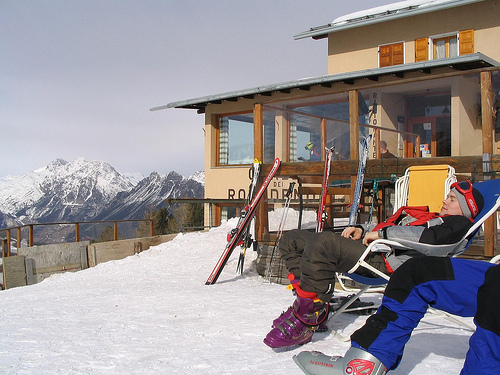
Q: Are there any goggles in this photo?
A: Yes, there are goggles.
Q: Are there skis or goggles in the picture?
A: Yes, there are goggles.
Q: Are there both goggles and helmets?
A: No, there are goggles but no helmets.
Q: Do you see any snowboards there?
A: No, there are no snowboards.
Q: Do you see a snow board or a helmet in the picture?
A: No, there are no snowboards or helmets.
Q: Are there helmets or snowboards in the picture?
A: No, there are no snowboards or helmets.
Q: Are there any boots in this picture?
A: Yes, there are boots.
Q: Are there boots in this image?
A: Yes, there are boots.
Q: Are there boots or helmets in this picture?
A: Yes, there are boots.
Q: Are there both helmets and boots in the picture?
A: No, there are boots but no helmets.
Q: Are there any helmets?
A: No, there are no helmets.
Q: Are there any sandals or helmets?
A: No, there are no helmets or sandals.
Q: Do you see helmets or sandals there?
A: No, there are no helmets or sandals.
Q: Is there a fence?
A: Yes, there is a fence.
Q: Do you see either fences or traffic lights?
A: Yes, there is a fence.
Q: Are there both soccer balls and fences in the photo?
A: No, there is a fence but no soccer balls.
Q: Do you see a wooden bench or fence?
A: Yes, there is a wood fence.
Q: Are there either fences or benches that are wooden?
A: Yes, the fence is wooden.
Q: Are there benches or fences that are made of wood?
A: Yes, the fence is made of wood.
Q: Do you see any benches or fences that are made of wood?
A: Yes, the fence is made of wood.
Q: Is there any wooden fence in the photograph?
A: Yes, there is a wood fence.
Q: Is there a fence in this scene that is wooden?
A: Yes, there is a fence that is wooden.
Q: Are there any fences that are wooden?
A: Yes, there is a fence that is wooden.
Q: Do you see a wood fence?
A: Yes, there is a fence that is made of wood.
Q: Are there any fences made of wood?
A: Yes, there is a fence that is made of wood.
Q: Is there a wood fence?
A: Yes, there is a fence that is made of wood.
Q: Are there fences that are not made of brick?
A: Yes, there is a fence that is made of wood.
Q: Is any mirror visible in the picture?
A: No, there are no mirrors.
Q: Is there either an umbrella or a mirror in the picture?
A: No, there are no mirrors or umbrellas.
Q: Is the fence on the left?
A: Yes, the fence is on the left of the image.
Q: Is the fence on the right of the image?
A: No, the fence is on the left of the image.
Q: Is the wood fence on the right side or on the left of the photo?
A: The fence is on the left of the image.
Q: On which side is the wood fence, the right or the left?
A: The fence is on the left of the image.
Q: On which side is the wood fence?
A: The fence is on the left of the image.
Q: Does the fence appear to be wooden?
A: Yes, the fence is wooden.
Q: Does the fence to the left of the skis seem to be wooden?
A: Yes, the fence is wooden.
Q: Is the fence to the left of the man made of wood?
A: Yes, the fence is made of wood.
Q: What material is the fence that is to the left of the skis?
A: The fence is made of wood.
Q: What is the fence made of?
A: The fence is made of wood.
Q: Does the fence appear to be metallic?
A: No, the fence is wooden.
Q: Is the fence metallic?
A: No, the fence is wooden.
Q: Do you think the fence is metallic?
A: No, the fence is wooden.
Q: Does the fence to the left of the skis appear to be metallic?
A: No, the fence is wooden.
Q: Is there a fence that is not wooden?
A: No, there is a fence but it is wooden.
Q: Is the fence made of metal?
A: No, the fence is made of wood.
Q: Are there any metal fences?
A: No, there is a fence but it is made of wood.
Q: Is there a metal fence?
A: No, there is a fence but it is made of wood.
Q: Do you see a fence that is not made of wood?
A: No, there is a fence but it is made of wood.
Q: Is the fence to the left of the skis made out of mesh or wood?
A: The fence is made of wood.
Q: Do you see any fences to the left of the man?
A: Yes, there is a fence to the left of the man.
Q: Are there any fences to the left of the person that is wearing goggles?
A: Yes, there is a fence to the left of the man.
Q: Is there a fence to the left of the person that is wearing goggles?
A: Yes, there is a fence to the left of the man.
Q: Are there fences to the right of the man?
A: No, the fence is to the left of the man.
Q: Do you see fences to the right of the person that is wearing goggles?
A: No, the fence is to the left of the man.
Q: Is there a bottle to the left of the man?
A: No, there is a fence to the left of the man.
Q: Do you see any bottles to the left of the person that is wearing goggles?
A: No, there is a fence to the left of the man.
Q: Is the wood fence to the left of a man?
A: Yes, the fence is to the left of a man.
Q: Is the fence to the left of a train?
A: No, the fence is to the left of a man.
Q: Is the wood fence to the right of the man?
A: No, the fence is to the left of the man.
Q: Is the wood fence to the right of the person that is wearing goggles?
A: No, the fence is to the left of the man.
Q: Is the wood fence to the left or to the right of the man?
A: The fence is to the left of the man.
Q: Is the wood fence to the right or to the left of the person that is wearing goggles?
A: The fence is to the left of the man.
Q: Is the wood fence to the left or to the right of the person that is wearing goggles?
A: The fence is to the left of the man.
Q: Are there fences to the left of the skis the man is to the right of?
A: Yes, there is a fence to the left of the skis.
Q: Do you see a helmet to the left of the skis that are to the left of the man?
A: No, there is a fence to the left of the skis.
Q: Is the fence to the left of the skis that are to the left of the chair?
A: Yes, the fence is to the left of the skis.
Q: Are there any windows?
A: Yes, there is a window.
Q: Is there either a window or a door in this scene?
A: Yes, there is a window.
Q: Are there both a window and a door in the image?
A: Yes, there are both a window and a door.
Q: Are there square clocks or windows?
A: Yes, there is a square window.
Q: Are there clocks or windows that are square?
A: Yes, the window is square.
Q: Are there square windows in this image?
A: Yes, there is a square window.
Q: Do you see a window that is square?
A: Yes, there is a window that is square.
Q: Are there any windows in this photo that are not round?
A: Yes, there is a square window.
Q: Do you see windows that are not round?
A: Yes, there is a square window.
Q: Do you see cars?
A: No, there are no cars.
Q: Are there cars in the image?
A: No, there are no cars.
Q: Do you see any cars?
A: No, there are no cars.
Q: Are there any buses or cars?
A: No, there are no cars or buses.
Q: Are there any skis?
A: Yes, there are skis.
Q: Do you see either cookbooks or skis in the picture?
A: Yes, there are skis.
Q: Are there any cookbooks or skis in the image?
A: Yes, there are skis.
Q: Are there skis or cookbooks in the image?
A: Yes, there are skis.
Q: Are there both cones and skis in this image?
A: No, there are skis but no cones.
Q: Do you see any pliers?
A: No, there are no pliers.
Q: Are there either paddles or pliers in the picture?
A: No, there are no pliers or paddles.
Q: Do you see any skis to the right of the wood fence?
A: Yes, there are skis to the right of the fence.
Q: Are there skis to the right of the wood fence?
A: Yes, there are skis to the right of the fence.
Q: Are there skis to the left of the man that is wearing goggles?
A: Yes, there are skis to the left of the man.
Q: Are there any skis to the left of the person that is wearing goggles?
A: Yes, there are skis to the left of the man.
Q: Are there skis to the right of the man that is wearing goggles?
A: No, the skis are to the left of the man.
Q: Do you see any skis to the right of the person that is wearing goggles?
A: No, the skis are to the left of the man.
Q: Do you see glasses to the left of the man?
A: No, there are skis to the left of the man.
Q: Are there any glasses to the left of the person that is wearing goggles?
A: No, there are skis to the left of the man.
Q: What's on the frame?
A: The skis are on the frame.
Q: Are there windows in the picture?
A: Yes, there are windows.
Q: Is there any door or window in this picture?
A: Yes, there are windows.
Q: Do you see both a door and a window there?
A: Yes, there are both a window and a door.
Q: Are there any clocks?
A: No, there are no clocks.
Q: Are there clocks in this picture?
A: No, there are no clocks.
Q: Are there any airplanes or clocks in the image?
A: No, there are no clocks or airplanes.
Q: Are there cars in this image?
A: No, there are no cars.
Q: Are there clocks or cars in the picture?
A: No, there are no cars or clocks.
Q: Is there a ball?
A: No, there are no balls.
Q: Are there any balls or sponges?
A: No, there are no balls or sponges.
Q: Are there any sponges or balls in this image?
A: No, there are no balls or sponges.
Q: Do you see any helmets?
A: No, there are no helmets.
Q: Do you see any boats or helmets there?
A: No, there are no helmets or boats.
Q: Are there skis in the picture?
A: Yes, there are skis.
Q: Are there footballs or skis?
A: Yes, there are skis.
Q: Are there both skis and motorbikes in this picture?
A: No, there are skis but no motorcycles.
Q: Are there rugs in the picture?
A: No, there are no rugs.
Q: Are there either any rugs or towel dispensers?
A: No, there are no rugs or towel dispensers.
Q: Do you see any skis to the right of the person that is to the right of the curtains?
A: Yes, there are skis to the right of the person.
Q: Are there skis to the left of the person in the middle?
A: No, the skis are to the right of the person.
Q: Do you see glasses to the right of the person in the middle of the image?
A: No, there are skis to the right of the person.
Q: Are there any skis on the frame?
A: Yes, there are skis on the frame.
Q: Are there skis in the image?
A: Yes, there are skis.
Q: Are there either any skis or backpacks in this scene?
A: Yes, there are skis.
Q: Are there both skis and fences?
A: Yes, there are both skis and a fence.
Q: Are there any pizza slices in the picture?
A: No, there are no pizza slices.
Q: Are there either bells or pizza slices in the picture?
A: No, there are no pizza slices or bells.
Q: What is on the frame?
A: The skis are on the frame.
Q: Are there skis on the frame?
A: Yes, there are skis on the frame.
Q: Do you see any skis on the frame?
A: Yes, there are skis on the frame.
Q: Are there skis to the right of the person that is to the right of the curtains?
A: Yes, there are skis to the right of the person.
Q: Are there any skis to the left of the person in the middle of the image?
A: No, the skis are to the right of the person.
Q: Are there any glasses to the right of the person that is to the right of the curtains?
A: No, there are skis to the right of the person.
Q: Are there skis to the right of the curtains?
A: Yes, there are skis to the right of the curtains.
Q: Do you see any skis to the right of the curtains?
A: Yes, there are skis to the right of the curtains.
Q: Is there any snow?
A: Yes, there is snow.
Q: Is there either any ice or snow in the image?
A: Yes, there is snow.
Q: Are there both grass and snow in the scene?
A: No, there is snow but no grass.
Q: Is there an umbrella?
A: No, there are no umbrellas.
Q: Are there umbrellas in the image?
A: No, there are no umbrellas.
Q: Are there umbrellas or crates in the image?
A: No, there are no umbrellas or crates.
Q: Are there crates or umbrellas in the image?
A: No, there are no umbrellas or crates.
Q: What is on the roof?
A: The snow is on the roof.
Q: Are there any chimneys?
A: No, there are no chimneys.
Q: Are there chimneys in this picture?
A: No, there are no chimneys.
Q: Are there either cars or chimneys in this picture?
A: No, there are no chimneys or cars.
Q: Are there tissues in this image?
A: No, there are no tissues.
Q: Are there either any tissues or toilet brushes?
A: No, there are no tissues or toilet brushes.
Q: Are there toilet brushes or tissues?
A: No, there are no tissues or toilet brushes.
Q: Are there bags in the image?
A: No, there are no bags.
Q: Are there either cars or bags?
A: No, there are no bags or cars.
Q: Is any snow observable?
A: Yes, there is snow.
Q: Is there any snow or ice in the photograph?
A: Yes, there is snow.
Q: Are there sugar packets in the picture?
A: No, there are no sugar packets.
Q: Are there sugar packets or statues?
A: No, there are no sugar packets or statues.